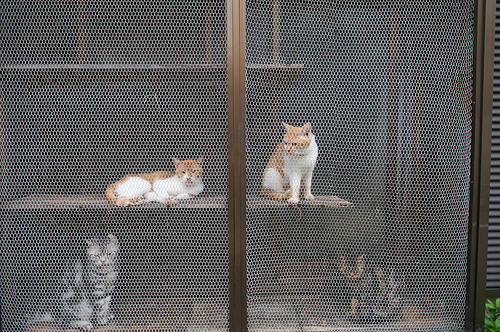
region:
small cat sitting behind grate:
[261, 121, 331, 206]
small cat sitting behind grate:
[110, 145, 205, 210]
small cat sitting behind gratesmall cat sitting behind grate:
[55, 231, 125, 317]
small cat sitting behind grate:
[330, 245, 405, 325]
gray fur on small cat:
[76, 262, 96, 288]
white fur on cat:
[160, 178, 182, 196]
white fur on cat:
[282, 150, 307, 176]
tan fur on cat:
[139, 156, 181, 185]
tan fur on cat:
[277, 127, 305, 150]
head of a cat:
[269, 112, 327, 156]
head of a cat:
[329, 231, 377, 286]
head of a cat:
[169, 146, 211, 188]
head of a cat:
[77, 221, 132, 269]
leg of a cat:
[155, 181, 179, 199]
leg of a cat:
[287, 169, 297, 200]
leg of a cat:
[303, 173, 318, 204]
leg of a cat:
[352, 293, 379, 323]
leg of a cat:
[65, 306, 107, 328]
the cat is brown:
[305, 231, 416, 320]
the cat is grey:
[26, 222, 141, 329]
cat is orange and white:
[260, 99, 325, 204]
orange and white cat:
[90, 158, 207, 205]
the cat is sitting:
[250, 122, 328, 196]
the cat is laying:
[105, 154, 210, 209]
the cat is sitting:
[22, 225, 125, 329]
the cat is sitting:
[331, 254, 398, 321]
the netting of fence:
[352, 30, 413, 109]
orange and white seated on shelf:
[258, 115, 319, 208]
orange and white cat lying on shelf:
[99, 151, 207, 206]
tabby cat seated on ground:
[330, 245, 407, 324]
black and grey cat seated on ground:
[18, 230, 121, 330]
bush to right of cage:
[481, 294, 498, 330]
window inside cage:
[3, 0, 297, 193]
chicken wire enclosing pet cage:
[4, 2, 464, 329]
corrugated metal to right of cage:
[480, 0, 498, 298]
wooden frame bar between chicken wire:
[223, 0, 250, 330]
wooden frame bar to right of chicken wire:
[462, 9, 497, 329]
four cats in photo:
[41, 71, 457, 331]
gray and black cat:
[29, 216, 140, 317]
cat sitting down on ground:
[295, 235, 417, 324]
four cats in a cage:
[13, 99, 463, 316]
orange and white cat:
[248, 94, 344, 199]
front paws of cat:
[277, 170, 329, 219]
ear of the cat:
[300, 115, 321, 140]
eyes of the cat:
[275, 133, 304, 154]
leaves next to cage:
[478, 293, 498, 321]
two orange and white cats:
[84, 93, 364, 225]